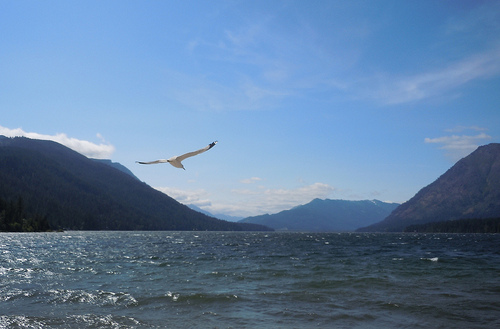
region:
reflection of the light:
[0, 283, 187, 304]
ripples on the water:
[43, 260, 182, 326]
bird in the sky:
[121, 124, 233, 184]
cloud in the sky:
[361, 44, 488, 122]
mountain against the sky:
[236, 190, 403, 225]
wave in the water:
[5, 280, 240, 312]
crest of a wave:
[426, 250, 443, 267]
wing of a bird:
[176, 138, 217, 162]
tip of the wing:
[206, 134, 220, 154]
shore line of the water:
[0, 221, 263, 248]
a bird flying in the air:
[69, 95, 321, 237]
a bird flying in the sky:
[112, 73, 271, 235]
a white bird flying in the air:
[125, 123, 272, 218]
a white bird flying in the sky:
[97, 119, 232, 196]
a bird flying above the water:
[82, 83, 374, 328]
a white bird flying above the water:
[107, 109, 322, 306]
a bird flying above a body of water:
[98, 103, 383, 324]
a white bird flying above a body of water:
[77, 123, 327, 323]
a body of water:
[83, 183, 380, 324]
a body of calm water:
[168, 261, 395, 328]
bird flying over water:
[129, 136, 219, 185]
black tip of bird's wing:
[207, 140, 218, 155]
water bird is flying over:
[18, 220, 466, 324]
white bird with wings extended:
[135, 142, 216, 174]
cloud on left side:
[2, 121, 124, 166]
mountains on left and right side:
[7, 127, 498, 247]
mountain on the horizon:
[239, 186, 395, 244]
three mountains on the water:
[9, 130, 484, 230]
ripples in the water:
[15, 225, 465, 322]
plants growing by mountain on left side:
[2, 187, 102, 224]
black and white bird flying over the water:
[135, 137, 218, 169]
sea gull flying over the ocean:
[136, 140, 218, 169]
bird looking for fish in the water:
[133, 140, 218, 169]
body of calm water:
[0, 229, 499, 326]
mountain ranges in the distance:
[0, 135, 497, 231]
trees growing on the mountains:
[1, 134, 498, 232]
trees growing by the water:
[1, 136, 498, 231]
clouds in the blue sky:
[1, 20, 486, 222]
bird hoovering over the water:
[135, 137, 219, 172]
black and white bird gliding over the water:
[133, 140, 218, 170]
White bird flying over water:
[131, 140, 218, 172]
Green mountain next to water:
[0, 129, 271, 231]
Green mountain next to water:
[354, 138, 499, 228]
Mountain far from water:
[237, 195, 405, 230]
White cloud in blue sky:
[0, 122, 118, 161]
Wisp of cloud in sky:
[335, 48, 482, 104]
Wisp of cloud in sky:
[170, 12, 304, 117]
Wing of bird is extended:
[132, 151, 167, 166]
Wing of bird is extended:
[177, 138, 219, 158]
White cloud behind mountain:
[225, 180, 332, 210]